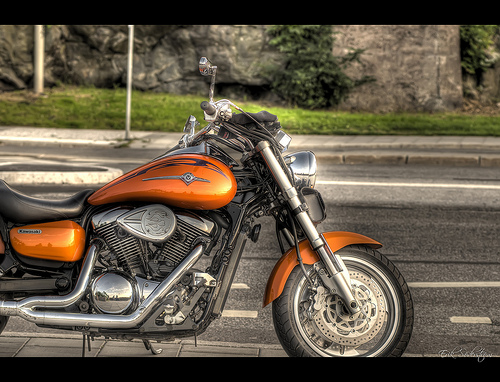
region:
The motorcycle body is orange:
[0, 58, 411, 355]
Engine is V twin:
[1, 204, 254, 344]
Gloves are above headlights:
[201, 105, 293, 158]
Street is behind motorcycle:
[0, 141, 499, 351]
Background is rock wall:
[1, 25, 498, 114]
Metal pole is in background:
[114, 21, 141, 144]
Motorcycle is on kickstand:
[1, 59, 421, 356]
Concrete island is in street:
[1, 148, 127, 190]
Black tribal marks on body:
[76, 149, 239, 195]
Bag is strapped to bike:
[265, 177, 336, 231]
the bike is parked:
[22, 95, 425, 380]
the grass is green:
[53, 102, 100, 118]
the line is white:
[368, 173, 466, 200]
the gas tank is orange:
[81, 153, 273, 228]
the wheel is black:
[272, 294, 319, 351]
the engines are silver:
[67, 195, 240, 361]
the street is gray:
[342, 205, 469, 258]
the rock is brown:
[336, 37, 496, 128]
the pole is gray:
[110, 45, 161, 138]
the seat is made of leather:
[2, 179, 132, 244]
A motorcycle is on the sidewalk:
[2, 68, 422, 378]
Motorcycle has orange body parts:
[7, 122, 382, 329]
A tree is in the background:
[256, 25, 496, 120]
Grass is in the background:
[20, 70, 495, 145]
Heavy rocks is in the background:
[5, 22, 496, 134]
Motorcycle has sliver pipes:
[0, 245, 210, 335]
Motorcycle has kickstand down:
[121, 315, 181, 355]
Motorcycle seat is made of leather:
[5, 160, 105, 235]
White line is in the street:
[325, 165, 495, 196]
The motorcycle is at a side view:
[3, 43, 437, 363]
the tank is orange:
[83, 139, 245, 228]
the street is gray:
[407, 221, 483, 266]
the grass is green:
[67, 90, 142, 122]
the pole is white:
[117, 30, 152, 156]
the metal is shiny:
[82, 263, 138, 325]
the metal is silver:
[78, 263, 150, 322]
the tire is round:
[262, 236, 440, 374]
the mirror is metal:
[177, 47, 242, 122]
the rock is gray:
[224, 29, 384, 109]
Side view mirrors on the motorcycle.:
[168, 53, 223, 137]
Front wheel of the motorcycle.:
[267, 240, 408, 355]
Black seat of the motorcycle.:
[0, 170, 90, 220]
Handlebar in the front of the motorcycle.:
[200, 96, 230, 126]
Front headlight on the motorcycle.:
[285, 143, 319, 197]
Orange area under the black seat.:
[10, 225, 85, 259]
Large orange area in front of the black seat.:
[90, 153, 236, 202]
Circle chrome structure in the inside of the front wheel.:
[307, 265, 386, 346]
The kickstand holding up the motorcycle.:
[122, 333, 163, 353]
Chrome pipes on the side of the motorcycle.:
[0, 236, 225, 333]